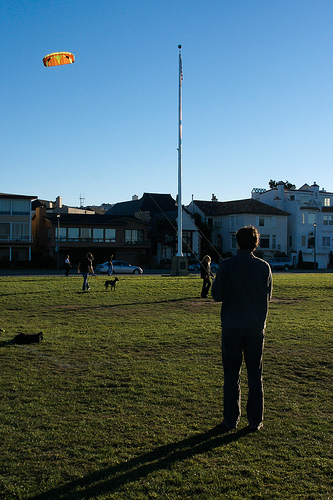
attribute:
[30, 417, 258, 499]
shadow of legs — of legs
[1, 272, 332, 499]
field of grass — grass's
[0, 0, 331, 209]
clear sky —  clear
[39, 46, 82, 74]
orange kite —  orange and yellow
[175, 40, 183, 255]
white flag pole —  tall,  white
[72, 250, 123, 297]
walking pet dog —  pet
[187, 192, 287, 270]
white house —   three story,  white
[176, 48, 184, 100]
american flag flat —  flat,  american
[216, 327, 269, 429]
person's legs —  person's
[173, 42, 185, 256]
flag pole — for Flag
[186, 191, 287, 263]
white apartment —  building,  White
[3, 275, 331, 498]
freshly cut grass —  Freshly,   cut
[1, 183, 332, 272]
apartment buildings —  buildings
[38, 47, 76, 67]
bright orange kite —  Bright orange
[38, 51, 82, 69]
parachute — yellow, orange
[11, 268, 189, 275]
road — grey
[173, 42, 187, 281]
pole — white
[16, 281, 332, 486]
grass — green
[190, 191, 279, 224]
roof — brown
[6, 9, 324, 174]
sky — blue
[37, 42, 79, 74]
kite — yellow, orange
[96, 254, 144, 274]
car — silver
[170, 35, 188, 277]
flag pole — tall